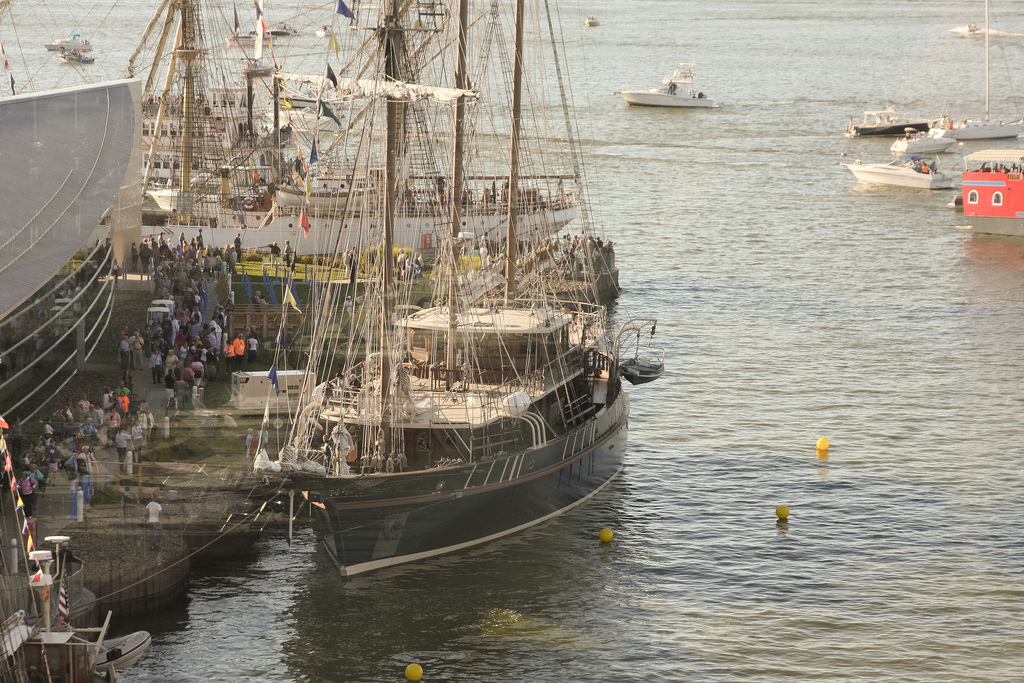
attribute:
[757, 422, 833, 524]
yellowballs — yellow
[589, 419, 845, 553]
yellowballs — yellow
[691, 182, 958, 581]
wate — calm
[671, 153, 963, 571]
water — blue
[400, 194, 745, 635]
ship — docked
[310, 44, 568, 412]
masts — tall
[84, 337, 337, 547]
dock — wooden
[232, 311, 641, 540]
boat — gray